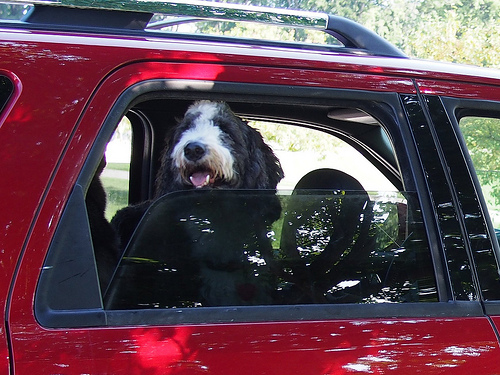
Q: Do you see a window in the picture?
A: Yes, there is a window.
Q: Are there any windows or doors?
A: Yes, there is a window.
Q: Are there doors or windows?
A: Yes, there is a window.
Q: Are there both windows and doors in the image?
A: Yes, there are both a window and a door.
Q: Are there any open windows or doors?
A: Yes, there is an open window.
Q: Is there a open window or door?
A: Yes, there is an open window.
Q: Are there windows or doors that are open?
A: Yes, the window is open.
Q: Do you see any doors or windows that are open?
A: Yes, the window is open.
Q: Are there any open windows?
A: Yes, there is an open window.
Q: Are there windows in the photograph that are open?
A: Yes, there is a window that is open.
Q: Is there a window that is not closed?
A: Yes, there is a open window.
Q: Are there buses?
A: No, there are no buses.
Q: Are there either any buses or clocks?
A: No, there are no buses or clocks.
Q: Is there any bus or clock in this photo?
A: No, there are no buses or clocks.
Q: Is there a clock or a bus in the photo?
A: No, there are no buses or clocks.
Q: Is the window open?
A: Yes, the window is open.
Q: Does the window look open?
A: Yes, the window is open.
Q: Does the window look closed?
A: No, the window is open.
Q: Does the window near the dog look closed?
A: No, the window is open.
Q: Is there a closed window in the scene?
A: No, there is a window but it is open.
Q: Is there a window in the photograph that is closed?
A: No, there is a window but it is open.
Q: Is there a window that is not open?
A: No, there is a window but it is open.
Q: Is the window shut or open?
A: The window is open.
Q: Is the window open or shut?
A: The window is open.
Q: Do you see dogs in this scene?
A: Yes, there is a dog.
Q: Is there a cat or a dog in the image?
A: Yes, there is a dog.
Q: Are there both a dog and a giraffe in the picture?
A: No, there is a dog but no giraffes.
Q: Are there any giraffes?
A: No, there are no giraffes.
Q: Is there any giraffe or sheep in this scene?
A: No, there are no giraffes or sheep.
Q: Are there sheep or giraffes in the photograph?
A: No, there are no giraffes or sheep.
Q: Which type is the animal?
A: The animal is a dog.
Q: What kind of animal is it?
A: The animal is a dog.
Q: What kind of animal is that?
A: This is a dog.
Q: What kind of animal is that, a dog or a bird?
A: This is a dog.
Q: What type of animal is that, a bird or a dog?
A: This is a dog.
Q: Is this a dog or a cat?
A: This is a dog.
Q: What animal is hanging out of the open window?
A: The dog is hanging out of the window.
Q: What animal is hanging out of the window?
A: The dog is hanging out of the window.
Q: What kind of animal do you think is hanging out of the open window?
A: The animal is a dog.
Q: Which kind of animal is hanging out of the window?
A: The animal is a dog.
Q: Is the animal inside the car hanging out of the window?
A: Yes, the dog is hanging out of the window.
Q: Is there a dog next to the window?
A: Yes, there is a dog next to the window.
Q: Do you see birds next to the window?
A: No, there is a dog next to the window.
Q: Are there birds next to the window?
A: No, there is a dog next to the window.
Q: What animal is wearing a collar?
A: The dog is wearing a collar.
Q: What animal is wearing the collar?
A: The dog is wearing a collar.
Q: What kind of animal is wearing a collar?
A: The animal is a dog.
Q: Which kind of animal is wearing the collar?
A: The animal is a dog.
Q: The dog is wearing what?
A: The dog is wearing a collar.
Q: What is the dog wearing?
A: The dog is wearing a collar.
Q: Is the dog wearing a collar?
A: Yes, the dog is wearing a collar.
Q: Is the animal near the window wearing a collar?
A: Yes, the dog is wearing a collar.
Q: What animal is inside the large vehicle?
A: The dog is inside the car.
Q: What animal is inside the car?
A: The dog is inside the car.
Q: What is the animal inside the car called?
A: The animal is a dog.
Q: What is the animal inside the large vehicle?
A: The animal is a dog.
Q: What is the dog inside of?
A: The dog is inside the car.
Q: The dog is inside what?
A: The dog is inside the car.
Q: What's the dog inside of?
A: The dog is inside the car.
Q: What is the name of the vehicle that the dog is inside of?
A: The vehicle is a car.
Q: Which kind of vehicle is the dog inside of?
A: The dog is inside the car.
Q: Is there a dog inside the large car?
A: Yes, there is a dog inside the car.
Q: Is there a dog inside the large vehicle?
A: Yes, there is a dog inside the car.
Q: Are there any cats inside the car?
A: No, there is a dog inside the car.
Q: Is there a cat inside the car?
A: No, there is a dog inside the car.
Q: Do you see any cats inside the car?
A: No, there is a dog inside the car.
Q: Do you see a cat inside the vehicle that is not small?
A: No, there is a dog inside the car.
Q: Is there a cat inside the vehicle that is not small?
A: No, there is a dog inside the car.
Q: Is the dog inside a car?
A: Yes, the dog is inside a car.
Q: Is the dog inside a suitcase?
A: No, the dog is inside a car.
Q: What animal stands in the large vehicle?
A: The dog stands in the car.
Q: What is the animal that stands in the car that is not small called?
A: The animal is a dog.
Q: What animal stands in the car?
A: The animal is a dog.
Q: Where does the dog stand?
A: The dog stands in the car.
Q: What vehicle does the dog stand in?
A: The dog stands in the car.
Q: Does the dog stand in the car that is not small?
A: Yes, the dog stands in the car.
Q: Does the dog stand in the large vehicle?
A: Yes, the dog stands in the car.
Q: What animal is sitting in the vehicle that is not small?
A: The dog is sitting in the car.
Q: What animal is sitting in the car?
A: The dog is sitting in the car.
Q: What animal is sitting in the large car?
A: The animal is a dog.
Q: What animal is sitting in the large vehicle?
A: The animal is a dog.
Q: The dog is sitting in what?
A: The dog is sitting in the car.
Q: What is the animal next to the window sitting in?
A: The dog is sitting in the car.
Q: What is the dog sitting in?
A: The dog is sitting in the car.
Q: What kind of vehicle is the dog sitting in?
A: The dog is sitting in the car.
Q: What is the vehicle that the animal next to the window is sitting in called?
A: The vehicle is a car.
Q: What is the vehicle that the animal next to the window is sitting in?
A: The vehicle is a car.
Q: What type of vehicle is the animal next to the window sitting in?
A: The dog is sitting in the car.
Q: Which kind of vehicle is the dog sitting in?
A: The dog is sitting in the car.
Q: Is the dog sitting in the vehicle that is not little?
A: Yes, the dog is sitting in the car.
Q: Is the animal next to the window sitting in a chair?
A: No, the dog is sitting in the car.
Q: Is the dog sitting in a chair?
A: No, the dog is sitting in the car.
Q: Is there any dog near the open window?
A: Yes, there is a dog near the window.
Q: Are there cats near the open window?
A: No, there is a dog near the window.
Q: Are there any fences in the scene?
A: No, there are no fences.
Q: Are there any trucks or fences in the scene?
A: No, there are no fences or trucks.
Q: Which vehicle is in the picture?
A: The vehicle is a car.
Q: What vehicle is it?
A: The vehicle is a car.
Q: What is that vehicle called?
A: This is a car.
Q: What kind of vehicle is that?
A: This is a car.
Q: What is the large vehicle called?
A: The vehicle is a car.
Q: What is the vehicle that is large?
A: The vehicle is a car.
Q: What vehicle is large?
A: The vehicle is a car.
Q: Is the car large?
A: Yes, the car is large.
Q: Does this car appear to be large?
A: Yes, the car is large.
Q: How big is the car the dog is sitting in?
A: The car is large.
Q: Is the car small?
A: No, the car is large.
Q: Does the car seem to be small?
A: No, the car is large.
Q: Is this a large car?
A: Yes, this is a large car.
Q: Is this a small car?
A: No, this is a large car.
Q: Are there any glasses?
A: No, there are no glasses.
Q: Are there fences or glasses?
A: No, there are no glasses or fences.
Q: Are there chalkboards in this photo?
A: No, there are no chalkboards.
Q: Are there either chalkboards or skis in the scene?
A: No, there are no chalkboards or skis.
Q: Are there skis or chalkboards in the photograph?
A: No, there are no chalkboards or skis.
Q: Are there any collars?
A: Yes, there is a collar.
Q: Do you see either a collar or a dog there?
A: Yes, there is a collar.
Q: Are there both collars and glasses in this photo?
A: No, there is a collar but no glasses.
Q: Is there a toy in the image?
A: No, there are no toys.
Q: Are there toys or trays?
A: No, there are no toys or trays.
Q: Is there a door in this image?
A: Yes, there is a door.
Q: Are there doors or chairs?
A: Yes, there is a door.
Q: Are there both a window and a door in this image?
A: Yes, there are both a door and a window.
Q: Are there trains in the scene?
A: No, there are no trains.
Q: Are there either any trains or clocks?
A: No, there are no trains or clocks.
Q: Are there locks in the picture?
A: No, there are no locks.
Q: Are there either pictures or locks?
A: No, there are no locks or pictures.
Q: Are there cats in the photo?
A: No, there are no cats.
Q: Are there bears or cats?
A: No, there are no cats or bears.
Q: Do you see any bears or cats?
A: No, there are no cats or bears.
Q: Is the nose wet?
A: Yes, the nose is wet.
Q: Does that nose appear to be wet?
A: Yes, the nose is wet.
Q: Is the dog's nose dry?
A: No, the nose is wet.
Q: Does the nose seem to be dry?
A: No, the nose is wet.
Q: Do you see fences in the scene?
A: No, there are no fences.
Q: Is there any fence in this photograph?
A: No, there are no fences.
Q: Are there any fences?
A: No, there are no fences.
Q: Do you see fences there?
A: No, there are no fences.